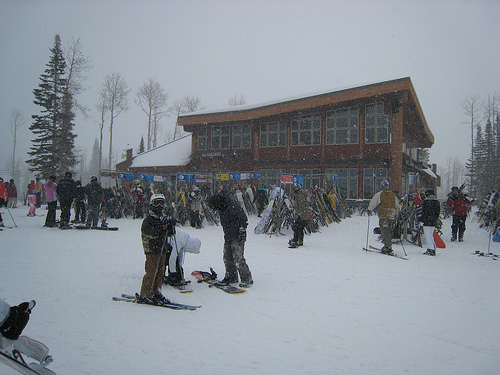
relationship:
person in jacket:
[152, 194, 224, 281] [162, 223, 230, 275]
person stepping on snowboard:
[206, 191, 254, 290] [193, 268, 245, 295]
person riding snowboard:
[284, 211, 312, 251] [75, 217, 118, 231]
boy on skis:
[139, 189, 174, 307] [117, 284, 201, 314]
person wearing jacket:
[22, 184, 53, 211] [37, 178, 60, 203]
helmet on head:
[147, 192, 167, 203] [141, 190, 178, 304]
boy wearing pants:
[139, 191, 174, 307] [136, 250, 171, 297]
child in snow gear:
[23, 186, 40, 213] [21, 196, 46, 212]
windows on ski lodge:
[193, 97, 394, 146] [116, 73, 441, 215]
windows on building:
[193, 97, 394, 146] [112, 74, 440, 216]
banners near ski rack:
[115, 172, 292, 182] [173, 182, 328, 229]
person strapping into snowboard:
[206, 191, 254, 290] [192, 266, 245, 298]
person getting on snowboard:
[206, 191, 254, 290] [191, 266, 246, 293]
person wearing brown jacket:
[358, 176, 408, 251] [373, 186, 405, 221]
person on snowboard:
[206, 191, 254, 290] [189, 261, 243, 298]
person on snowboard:
[42, 174, 52, 222] [32, 222, 67, 229]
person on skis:
[138, 182, 193, 317] [112, 283, 202, 313]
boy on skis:
[139, 191, 174, 307] [109, 289, 205, 318]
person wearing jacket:
[368, 177, 403, 254] [367, 190, 404, 220]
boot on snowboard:
[165, 262, 188, 285] [170, 279, 195, 294]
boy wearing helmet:
[139, 191, 174, 307] [109, 184, 173, 203]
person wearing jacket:
[42, 174, 52, 222] [41, 163, 62, 216]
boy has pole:
[139, 191, 174, 307] [172, 227, 192, 291]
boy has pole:
[139, 191, 174, 307] [146, 236, 173, 301]